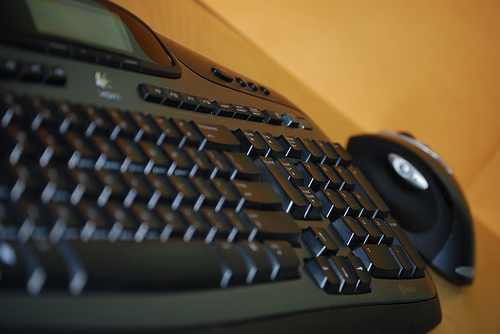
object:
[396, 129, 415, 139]
scroll wheel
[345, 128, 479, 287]
mouse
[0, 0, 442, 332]
keyboard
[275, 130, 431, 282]
numeric keypad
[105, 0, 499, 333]
desk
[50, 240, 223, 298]
space bar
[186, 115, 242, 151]
keys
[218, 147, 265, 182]
keys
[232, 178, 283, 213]
keys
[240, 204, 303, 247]
keys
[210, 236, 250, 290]
keys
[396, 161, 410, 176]
button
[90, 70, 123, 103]
logo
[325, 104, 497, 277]
right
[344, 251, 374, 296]
right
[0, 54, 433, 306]
out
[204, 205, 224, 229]
alphanumeric